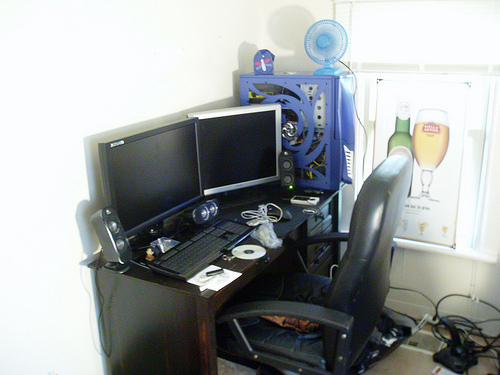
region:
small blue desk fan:
[296, 17, 353, 79]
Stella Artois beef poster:
[379, 77, 461, 252]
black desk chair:
[213, 151, 420, 373]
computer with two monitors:
[88, 105, 286, 280]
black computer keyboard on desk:
[145, 212, 250, 288]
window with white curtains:
[333, 3, 498, 264]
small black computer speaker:
[91, 206, 136, 278]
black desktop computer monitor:
[93, 110, 198, 243]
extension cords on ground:
[380, 283, 495, 371]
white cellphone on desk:
[288, 189, 320, 211]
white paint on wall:
[6, 225, 38, 257]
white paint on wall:
[1, 174, 23, 193]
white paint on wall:
[36, 158, 70, 187]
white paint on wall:
[52, 225, 88, 271]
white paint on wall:
[60, 93, 87, 115]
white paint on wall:
[112, 51, 142, 92]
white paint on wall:
[156, 65, 186, 89]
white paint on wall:
[199, 58, 231, 107]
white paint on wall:
[52, 324, 107, 362]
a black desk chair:
[221, 146, 414, 373]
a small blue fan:
[303, 17, 351, 76]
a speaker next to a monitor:
[88, 206, 133, 267]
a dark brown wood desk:
[86, 186, 343, 373]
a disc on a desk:
[230, 241, 264, 262]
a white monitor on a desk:
[188, 101, 286, 195]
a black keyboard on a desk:
[143, 214, 255, 281]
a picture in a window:
[365, 76, 475, 250]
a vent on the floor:
[401, 327, 454, 354]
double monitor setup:
[90, 101, 298, 222]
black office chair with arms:
[230, 151, 400, 371]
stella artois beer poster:
[376, 88, 456, 239]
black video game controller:
[434, 310, 479, 372]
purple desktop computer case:
[242, 68, 359, 190]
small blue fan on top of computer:
[296, 10, 349, 77]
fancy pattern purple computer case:
[236, 68, 360, 188]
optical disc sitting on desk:
[230, 240, 268, 262]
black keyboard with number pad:
[147, 214, 257, 281]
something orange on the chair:
[265, 314, 320, 333]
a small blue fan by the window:
[300, 13, 351, 81]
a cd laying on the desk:
[227, 238, 269, 264]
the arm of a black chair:
[206, 295, 359, 332]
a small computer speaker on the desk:
[84, 200, 135, 278]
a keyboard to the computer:
[137, 215, 258, 282]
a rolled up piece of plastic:
[246, 216, 284, 251]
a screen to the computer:
[92, 110, 209, 260]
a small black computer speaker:
[274, 144, 301, 204]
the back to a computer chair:
[306, 145, 420, 374]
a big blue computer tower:
[233, 65, 362, 201]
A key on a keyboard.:
[190, 255, 197, 259]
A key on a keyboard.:
[192, 248, 198, 258]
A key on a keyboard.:
[210, 240, 214, 244]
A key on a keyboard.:
[206, 237, 211, 241]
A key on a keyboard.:
[231, 223, 236, 228]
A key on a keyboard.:
[226, 232, 231, 237]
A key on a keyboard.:
[182, 253, 187, 257]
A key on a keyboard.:
[196, 247, 203, 249]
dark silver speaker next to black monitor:
[89, 116, 206, 275]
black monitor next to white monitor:
[98, 103, 282, 238]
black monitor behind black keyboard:
[98, 116, 258, 282]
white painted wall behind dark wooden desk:
[1, 1, 341, 373]